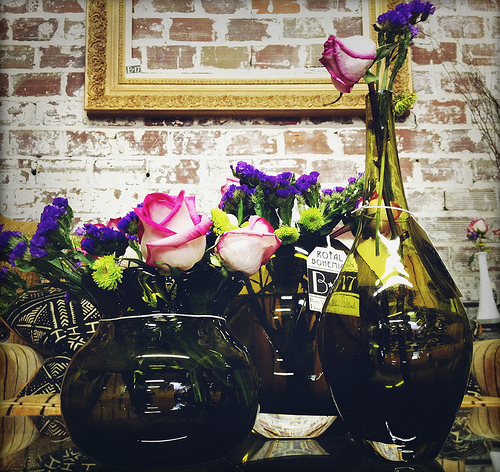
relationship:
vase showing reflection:
[60, 310, 255, 470] [135, 352, 191, 363]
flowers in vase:
[322, 0, 433, 94] [313, 91, 474, 467]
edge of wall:
[73, 1, 88, 111] [2, 0, 499, 301]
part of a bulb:
[324, 415, 334, 431] [250, 413, 340, 440]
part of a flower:
[92, 255, 106, 287] [91, 255, 121, 290]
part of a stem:
[394, 36, 410, 58] [373, 36, 413, 246]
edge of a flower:
[110, 255, 124, 289] [91, 255, 121, 290]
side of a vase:
[315, 281, 336, 404] [313, 91, 474, 467]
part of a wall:
[0, 0, 39, 18] [2, 0, 499, 301]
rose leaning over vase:
[319, 33, 377, 92] [313, 91, 474, 467]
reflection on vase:
[135, 352, 191, 363] [60, 310, 255, 470]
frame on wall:
[84, 0, 411, 116] [2, 0, 499, 301]